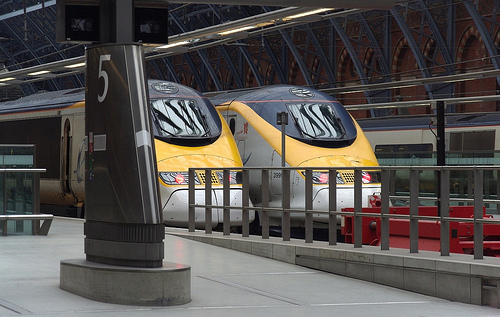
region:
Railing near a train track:
[186, 160, 498, 259]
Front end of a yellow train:
[241, 82, 387, 228]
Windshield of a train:
[151, 95, 208, 140]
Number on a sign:
[94, 53, 113, 101]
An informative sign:
[82, 38, 167, 264]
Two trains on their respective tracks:
[2, 88, 387, 233]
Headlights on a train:
[158, 167, 244, 186]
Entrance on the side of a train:
[58, 119, 76, 201]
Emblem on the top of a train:
[151, 78, 182, 95]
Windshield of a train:
[288, 102, 343, 142]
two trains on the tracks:
[0, 65, 428, 242]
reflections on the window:
[289, 101, 346, 141]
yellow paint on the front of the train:
[146, 96, 251, 193]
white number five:
[91, 53, 126, 109]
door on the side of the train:
[48, 110, 78, 192]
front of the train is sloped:
[248, 80, 395, 221]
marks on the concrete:
[143, 290, 182, 304]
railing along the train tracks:
[181, 159, 498, 253]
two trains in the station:
[0, 0, 499, 316]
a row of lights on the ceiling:
[0, 0, 332, 92]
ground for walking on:
[218, 260, 292, 315]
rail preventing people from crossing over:
[187, 165, 497, 237]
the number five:
[91, 51, 113, 101]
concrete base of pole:
[54, 248, 196, 308]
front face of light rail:
[227, 85, 382, 200]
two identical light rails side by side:
[144, 76, 388, 221]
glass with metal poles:
[0, 165, 52, 231]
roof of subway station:
[370, 4, 475, 79]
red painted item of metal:
[338, 204, 490, 240]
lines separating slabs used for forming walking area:
[220, 274, 304, 308]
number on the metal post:
[91, 50, 115, 101]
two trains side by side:
[139, 75, 381, 230]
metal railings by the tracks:
[190, 170, 482, 262]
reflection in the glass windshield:
[150, 91, 210, 133]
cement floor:
[230, 256, 312, 315]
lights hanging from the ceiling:
[189, 12, 285, 50]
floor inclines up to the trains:
[211, 234, 384, 304]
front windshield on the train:
[281, 93, 351, 136]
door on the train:
[56, 122, 73, 187]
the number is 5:
[82, 45, 117, 105]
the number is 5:
[76, 51, 118, 113]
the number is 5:
[72, 40, 110, 113]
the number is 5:
[77, 41, 117, 104]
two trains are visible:
[151, 74, 418, 270]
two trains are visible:
[145, 62, 397, 255]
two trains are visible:
[133, 59, 365, 276]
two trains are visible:
[143, 62, 379, 259]